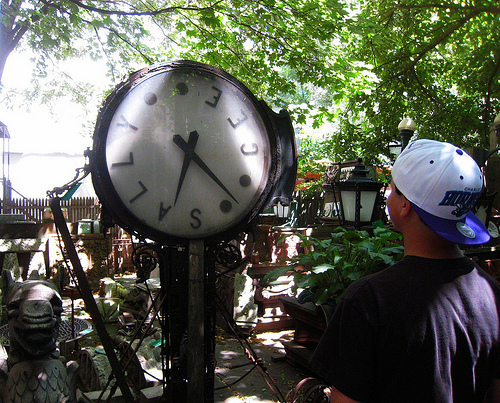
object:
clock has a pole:
[148, 245, 220, 402]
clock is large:
[88, 60, 284, 246]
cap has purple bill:
[416, 210, 491, 248]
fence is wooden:
[111, 226, 136, 278]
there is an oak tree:
[295, 1, 499, 215]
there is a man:
[306, 138, 500, 402]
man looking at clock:
[90, 60, 500, 402]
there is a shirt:
[300, 253, 498, 402]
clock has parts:
[268, 107, 298, 208]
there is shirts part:
[303, 269, 383, 402]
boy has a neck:
[397, 221, 471, 262]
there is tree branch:
[35, 0, 157, 66]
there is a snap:
[0, 0, 498, 402]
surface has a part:
[200, 77, 267, 176]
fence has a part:
[27, 198, 47, 228]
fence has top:
[1, 196, 100, 209]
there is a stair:
[0, 175, 44, 225]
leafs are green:
[316, 105, 331, 116]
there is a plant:
[257, 225, 403, 312]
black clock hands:
[170, 134, 242, 208]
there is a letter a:
[154, 202, 172, 225]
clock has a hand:
[170, 130, 202, 209]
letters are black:
[202, 83, 224, 109]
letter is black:
[203, 86, 221, 109]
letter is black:
[238, 141, 261, 158]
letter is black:
[113, 114, 141, 131]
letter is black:
[187, 207, 204, 231]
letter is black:
[109, 151, 136, 171]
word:
[106, 113, 204, 232]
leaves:
[248, 23, 254, 27]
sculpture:
[0, 278, 80, 402]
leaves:
[440, 116, 452, 123]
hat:
[389, 138, 490, 248]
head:
[384, 139, 485, 236]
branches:
[371, 0, 499, 92]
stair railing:
[0, 178, 43, 226]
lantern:
[335, 159, 382, 233]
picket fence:
[0, 196, 103, 223]